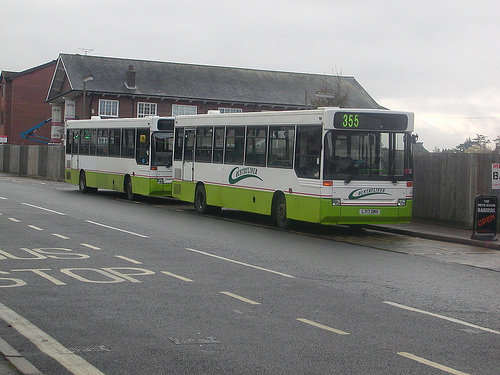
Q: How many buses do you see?
A: 2 buses.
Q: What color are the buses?
A: The buses are green and white.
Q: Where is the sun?
A: Behind the clouds.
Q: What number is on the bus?
A: The numbers 355.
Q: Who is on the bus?
A: No one.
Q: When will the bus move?
A: When the bus driver gets there.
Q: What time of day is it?
A: Late afternoon.